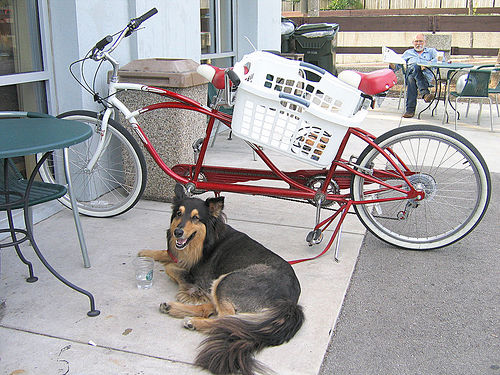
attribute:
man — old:
[386, 32, 446, 120]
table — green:
[0, 110, 102, 321]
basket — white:
[232, 49, 367, 171]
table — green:
[0, 114, 102, 159]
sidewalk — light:
[0, 103, 498, 373]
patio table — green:
[1, 106, 107, 319]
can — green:
[290, 23, 338, 78]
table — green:
[415, 61, 472, 122]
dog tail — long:
[212, 307, 304, 373]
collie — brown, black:
[134, 178, 309, 373]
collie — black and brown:
[162, 192, 283, 363]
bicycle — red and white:
[34, 6, 493, 253]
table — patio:
[5, 99, 115, 236]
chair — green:
[2, 147, 72, 246]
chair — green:
[454, 53, 490, 103]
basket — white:
[234, 39, 376, 170]